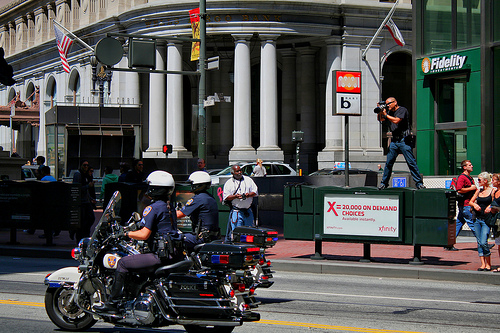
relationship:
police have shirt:
[94, 170, 180, 315] [142, 201, 179, 243]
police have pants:
[117, 163, 258, 271] [123, 253, 160, 270]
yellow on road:
[276, 312, 358, 331] [316, 284, 433, 323]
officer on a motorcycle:
[177, 170, 220, 241] [38, 189, 260, 331]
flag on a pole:
[45, 27, 78, 79] [48, 16, 100, 52]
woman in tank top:
[467, 164, 497, 271] [469, 187, 497, 217]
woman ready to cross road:
[467, 164, 497, 271] [0, 240, 497, 330]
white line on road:
[259, 285, 474, 310] [0, 252, 499, 331]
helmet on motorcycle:
[182, 166, 215, 193] [52, 209, 245, 319]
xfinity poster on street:
[320, 192, 404, 243] [279, 235, 466, 305]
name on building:
[420, 42, 468, 79] [275, 52, 395, 82]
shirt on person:
[455, 171, 477, 205] [454, 159, 482, 256]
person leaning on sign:
[454, 159, 482, 256] [318, 195, 400, 240]